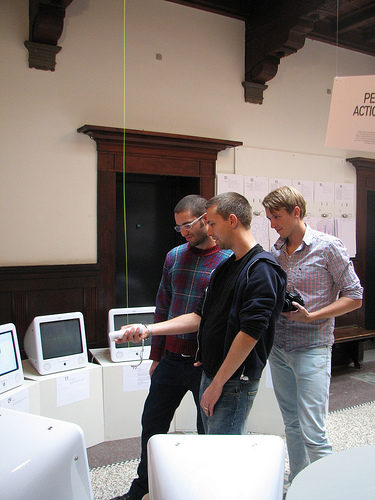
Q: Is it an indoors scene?
A: Yes, it is indoors.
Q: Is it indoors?
A: Yes, it is indoors.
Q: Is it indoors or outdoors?
A: It is indoors.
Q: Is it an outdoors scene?
A: No, it is indoors.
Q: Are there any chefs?
A: No, there are no chefs.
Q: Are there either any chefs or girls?
A: No, there are no chefs or girls.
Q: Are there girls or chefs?
A: No, there are no chefs or girls.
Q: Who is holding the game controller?
A: The man is holding the game controller.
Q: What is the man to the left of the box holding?
A: The man is holding the game controller.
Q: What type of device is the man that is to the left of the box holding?
A: The man is holding the game controller.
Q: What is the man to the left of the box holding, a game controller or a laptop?
A: The man is holding a game controller.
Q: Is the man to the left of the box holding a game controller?
A: Yes, the man is holding a game controller.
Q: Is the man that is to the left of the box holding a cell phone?
A: No, the man is holding a game controller.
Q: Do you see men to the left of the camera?
A: Yes, there is a man to the left of the camera.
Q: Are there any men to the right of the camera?
A: No, the man is to the left of the camera.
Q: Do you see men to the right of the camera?
A: No, the man is to the left of the camera.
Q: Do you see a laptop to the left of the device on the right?
A: No, there is a man to the left of the camera.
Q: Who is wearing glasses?
A: The man is wearing glasses.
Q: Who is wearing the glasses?
A: The man is wearing glasses.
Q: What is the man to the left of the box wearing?
A: The man is wearing glasses.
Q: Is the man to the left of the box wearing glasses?
A: Yes, the man is wearing glasses.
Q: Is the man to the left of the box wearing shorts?
A: No, the man is wearing glasses.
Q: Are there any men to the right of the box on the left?
A: Yes, there is a man to the right of the box.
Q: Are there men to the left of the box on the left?
A: No, the man is to the right of the box.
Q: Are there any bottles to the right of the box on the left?
A: No, there is a man to the right of the box.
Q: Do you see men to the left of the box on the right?
A: Yes, there is a man to the left of the box.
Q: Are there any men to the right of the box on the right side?
A: No, the man is to the left of the box.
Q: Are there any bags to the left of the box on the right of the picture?
A: No, there is a man to the left of the box.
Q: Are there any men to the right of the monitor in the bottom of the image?
A: Yes, there is a man to the right of the monitor.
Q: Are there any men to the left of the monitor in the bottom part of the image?
A: No, the man is to the right of the monitor.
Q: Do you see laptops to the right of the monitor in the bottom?
A: No, there is a man to the right of the monitor.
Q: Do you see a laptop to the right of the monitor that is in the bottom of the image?
A: No, there is a man to the right of the monitor.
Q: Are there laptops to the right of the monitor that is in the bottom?
A: No, there is a man to the right of the monitor.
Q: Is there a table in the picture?
A: Yes, there is a table.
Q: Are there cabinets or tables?
A: Yes, there is a table.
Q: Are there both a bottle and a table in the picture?
A: No, there is a table but no bottles.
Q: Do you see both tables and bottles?
A: No, there is a table but no bottles.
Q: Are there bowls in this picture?
A: No, there are no bowls.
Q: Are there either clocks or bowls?
A: No, there are no bowls or clocks.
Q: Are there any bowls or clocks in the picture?
A: No, there are no bowls or clocks.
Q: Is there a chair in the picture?
A: No, there are no chairs.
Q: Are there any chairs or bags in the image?
A: No, there are no chairs or bags.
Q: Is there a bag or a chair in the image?
A: No, there are no chairs or bags.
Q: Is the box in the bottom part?
A: Yes, the box is in the bottom of the image.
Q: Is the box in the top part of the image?
A: No, the box is in the bottom of the image.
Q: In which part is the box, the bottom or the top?
A: The box is in the bottom of the image.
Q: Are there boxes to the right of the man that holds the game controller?
A: Yes, there is a box to the right of the man.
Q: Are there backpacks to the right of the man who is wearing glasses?
A: No, there is a box to the right of the man.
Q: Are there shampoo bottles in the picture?
A: No, there are no shampoo bottles.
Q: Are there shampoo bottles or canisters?
A: No, there are no shampoo bottles or canisters.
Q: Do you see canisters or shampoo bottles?
A: No, there are no shampoo bottles or canisters.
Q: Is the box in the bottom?
A: Yes, the box is in the bottom of the image.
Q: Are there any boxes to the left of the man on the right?
A: Yes, there is a box to the left of the man.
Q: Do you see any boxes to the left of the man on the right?
A: Yes, there is a box to the left of the man.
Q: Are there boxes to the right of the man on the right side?
A: No, the box is to the left of the man.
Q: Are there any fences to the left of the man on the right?
A: No, there is a box to the left of the man.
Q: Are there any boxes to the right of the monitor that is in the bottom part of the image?
A: Yes, there is a box to the right of the monitor.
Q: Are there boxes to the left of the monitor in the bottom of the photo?
A: No, the box is to the right of the monitor.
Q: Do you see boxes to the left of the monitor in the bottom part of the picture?
A: No, the box is to the right of the monitor.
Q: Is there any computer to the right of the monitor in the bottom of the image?
A: No, there is a box to the right of the monitor.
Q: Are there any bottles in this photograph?
A: No, there are no bottles.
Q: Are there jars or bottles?
A: No, there are no bottles or jars.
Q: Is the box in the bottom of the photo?
A: Yes, the box is in the bottom of the image.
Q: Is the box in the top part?
A: No, the box is in the bottom of the image.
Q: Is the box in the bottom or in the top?
A: The box is in the bottom of the image.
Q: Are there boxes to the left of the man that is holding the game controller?
A: Yes, there is a box to the left of the man.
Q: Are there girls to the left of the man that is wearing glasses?
A: No, there is a box to the left of the man.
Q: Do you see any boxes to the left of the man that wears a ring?
A: Yes, there is a box to the left of the man.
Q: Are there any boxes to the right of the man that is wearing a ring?
A: No, the box is to the left of the man.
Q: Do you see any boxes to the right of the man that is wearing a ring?
A: No, the box is to the left of the man.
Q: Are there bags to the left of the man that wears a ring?
A: No, there is a box to the left of the man.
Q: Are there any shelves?
A: No, there are no shelves.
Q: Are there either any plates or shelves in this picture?
A: No, there are no shelves or plates.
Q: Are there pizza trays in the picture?
A: No, there are no pizza trays.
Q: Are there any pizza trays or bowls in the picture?
A: No, there are no pizza trays or bowls.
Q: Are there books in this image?
A: No, there are no books.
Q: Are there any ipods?
A: No, there are no ipods.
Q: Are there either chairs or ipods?
A: No, there are no ipods or chairs.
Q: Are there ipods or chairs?
A: No, there are no ipods or chairs.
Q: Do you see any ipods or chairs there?
A: No, there are no ipods or chairs.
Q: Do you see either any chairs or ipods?
A: No, there are no ipods or chairs.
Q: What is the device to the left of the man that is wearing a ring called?
A: The device is a monitor.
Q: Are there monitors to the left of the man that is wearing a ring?
A: Yes, there is a monitor to the left of the man.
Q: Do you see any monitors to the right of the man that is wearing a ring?
A: No, the monitor is to the left of the man.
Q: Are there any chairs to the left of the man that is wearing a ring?
A: No, there is a monitor to the left of the man.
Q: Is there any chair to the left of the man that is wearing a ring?
A: No, there is a monitor to the left of the man.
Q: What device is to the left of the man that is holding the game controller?
A: The device is a monitor.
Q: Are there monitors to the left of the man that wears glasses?
A: Yes, there is a monitor to the left of the man.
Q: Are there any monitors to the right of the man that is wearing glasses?
A: No, the monitor is to the left of the man.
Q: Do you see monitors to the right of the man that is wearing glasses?
A: No, the monitor is to the left of the man.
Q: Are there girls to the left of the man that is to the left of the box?
A: No, there is a monitor to the left of the man.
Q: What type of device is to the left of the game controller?
A: The device is a monitor.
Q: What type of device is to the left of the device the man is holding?
A: The device is a monitor.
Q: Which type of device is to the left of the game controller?
A: The device is a monitor.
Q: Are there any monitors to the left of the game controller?
A: Yes, there is a monitor to the left of the game controller.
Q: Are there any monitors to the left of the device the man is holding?
A: Yes, there is a monitor to the left of the game controller.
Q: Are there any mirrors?
A: No, there are no mirrors.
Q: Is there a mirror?
A: No, there are no mirrors.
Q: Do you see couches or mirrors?
A: No, there are no mirrors or couches.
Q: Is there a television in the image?
A: Yes, there is a television.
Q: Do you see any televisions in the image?
A: Yes, there is a television.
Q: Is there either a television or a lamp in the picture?
A: Yes, there is a television.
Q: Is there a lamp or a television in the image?
A: Yes, there is a television.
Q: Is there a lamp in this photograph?
A: No, there are no lamps.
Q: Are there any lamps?
A: No, there are no lamps.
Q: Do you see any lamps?
A: No, there are no lamps.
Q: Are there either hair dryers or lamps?
A: No, there are no lamps or hair dryers.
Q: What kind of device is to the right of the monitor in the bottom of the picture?
A: The device is a television.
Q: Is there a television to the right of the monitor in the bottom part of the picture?
A: Yes, there is a television to the right of the monitor.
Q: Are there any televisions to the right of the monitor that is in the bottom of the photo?
A: Yes, there is a television to the right of the monitor.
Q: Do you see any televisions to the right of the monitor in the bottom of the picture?
A: Yes, there is a television to the right of the monitor.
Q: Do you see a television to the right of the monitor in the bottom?
A: Yes, there is a television to the right of the monitor.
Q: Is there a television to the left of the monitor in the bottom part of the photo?
A: No, the television is to the right of the monitor.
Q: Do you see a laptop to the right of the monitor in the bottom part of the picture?
A: No, there is a television to the right of the monitor.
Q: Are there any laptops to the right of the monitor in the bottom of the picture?
A: No, there is a television to the right of the monitor.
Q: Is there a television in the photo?
A: Yes, there is a television.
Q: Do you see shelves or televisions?
A: Yes, there is a television.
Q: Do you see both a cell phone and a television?
A: No, there is a television but no cell phones.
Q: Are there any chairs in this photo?
A: No, there are no chairs.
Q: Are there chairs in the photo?
A: No, there are no chairs.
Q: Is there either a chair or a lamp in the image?
A: No, there are no chairs or lamps.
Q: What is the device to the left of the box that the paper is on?
A: The device is a television.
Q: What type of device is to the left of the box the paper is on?
A: The device is a television.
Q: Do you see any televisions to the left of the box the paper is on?
A: Yes, there is a television to the left of the box.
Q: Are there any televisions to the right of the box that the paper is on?
A: No, the television is to the left of the box.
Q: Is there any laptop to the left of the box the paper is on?
A: No, there is a television to the left of the box.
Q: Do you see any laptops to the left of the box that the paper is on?
A: No, there is a television to the left of the box.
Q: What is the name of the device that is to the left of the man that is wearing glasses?
A: The device is a television.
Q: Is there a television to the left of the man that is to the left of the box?
A: Yes, there is a television to the left of the man.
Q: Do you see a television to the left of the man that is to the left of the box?
A: Yes, there is a television to the left of the man.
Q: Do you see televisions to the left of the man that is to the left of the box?
A: Yes, there is a television to the left of the man.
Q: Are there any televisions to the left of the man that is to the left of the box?
A: Yes, there is a television to the left of the man.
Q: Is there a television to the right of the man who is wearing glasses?
A: No, the television is to the left of the man.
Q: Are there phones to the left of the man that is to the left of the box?
A: No, there is a television to the left of the man.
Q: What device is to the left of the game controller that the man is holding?
A: The device is a television.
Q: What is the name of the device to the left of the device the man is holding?
A: The device is a television.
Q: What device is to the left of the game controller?
A: The device is a television.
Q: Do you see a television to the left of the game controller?
A: Yes, there is a television to the left of the game controller.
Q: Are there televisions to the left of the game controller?
A: Yes, there is a television to the left of the game controller.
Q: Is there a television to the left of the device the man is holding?
A: Yes, there is a television to the left of the game controller.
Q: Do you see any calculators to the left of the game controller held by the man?
A: No, there is a television to the left of the game controller.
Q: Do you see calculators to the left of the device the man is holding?
A: No, there is a television to the left of the game controller.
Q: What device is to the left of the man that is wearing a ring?
A: The device is a television.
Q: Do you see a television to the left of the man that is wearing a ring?
A: Yes, there is a television to the left of the man.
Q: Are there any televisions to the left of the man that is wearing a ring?
A: Yes, there is a television to the left of the man.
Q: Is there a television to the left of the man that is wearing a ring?
A: Yes, there is a television to the left of the man.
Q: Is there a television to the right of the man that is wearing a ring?
A: No, the television is to the left of the man.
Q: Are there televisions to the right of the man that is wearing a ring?
A: No, the television is to the left of the man.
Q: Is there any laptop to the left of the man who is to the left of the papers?
A: No, there is a television to the left of the man.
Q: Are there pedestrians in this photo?
A: No, there are no pedestrians.